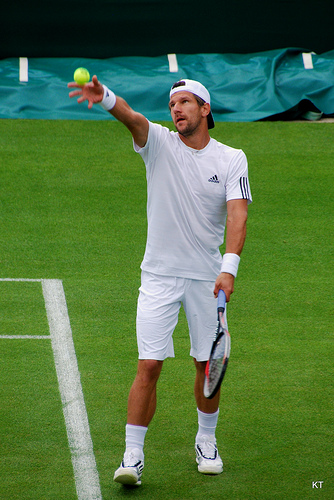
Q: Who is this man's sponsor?
A: ADIDAS.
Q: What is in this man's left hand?
A: Racket.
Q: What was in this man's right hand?
A: Tennis ball.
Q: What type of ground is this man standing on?
A: Astro turf.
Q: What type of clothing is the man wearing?
A: Athletic.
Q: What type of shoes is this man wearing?
A: Sneaker.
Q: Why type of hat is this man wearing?
A: Baseball cap.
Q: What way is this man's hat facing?
A: Backwards.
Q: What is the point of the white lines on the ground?
A: Boundaries.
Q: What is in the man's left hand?
A: Tennis racket.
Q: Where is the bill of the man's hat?
A: On the back of his head.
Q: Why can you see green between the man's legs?
A: Because he has his feet spread apart.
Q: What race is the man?
A: Caucasian.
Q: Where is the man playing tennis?
A: On a tennis court.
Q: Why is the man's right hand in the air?
A: He is catching the ball.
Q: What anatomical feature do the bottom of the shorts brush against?
A: Knees.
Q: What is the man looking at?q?
A: The ball.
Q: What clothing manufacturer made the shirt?
A: Adidas.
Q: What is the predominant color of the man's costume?
A: White.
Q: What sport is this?
A: Tennis.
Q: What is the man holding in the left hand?
A: Tennis racket.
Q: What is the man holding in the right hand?
A: Tennis ball.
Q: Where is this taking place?
A: Tennis court.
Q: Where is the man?
A: Tennis court.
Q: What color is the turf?
A: Green.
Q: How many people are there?
A: One.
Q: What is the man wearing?
A: Shorts.